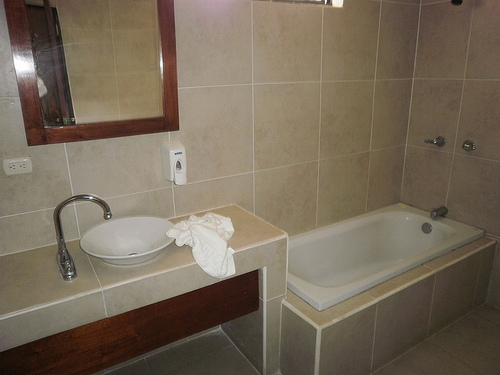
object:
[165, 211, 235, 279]
towel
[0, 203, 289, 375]
counter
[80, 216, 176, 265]
sink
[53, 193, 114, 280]
faucet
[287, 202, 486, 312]
tub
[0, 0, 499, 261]
wall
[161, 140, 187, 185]
soap dispenser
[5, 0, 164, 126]
mirror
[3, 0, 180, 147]
wood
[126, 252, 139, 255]
drain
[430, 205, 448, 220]
faucet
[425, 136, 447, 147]
handle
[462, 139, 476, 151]
handle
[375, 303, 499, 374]
floor